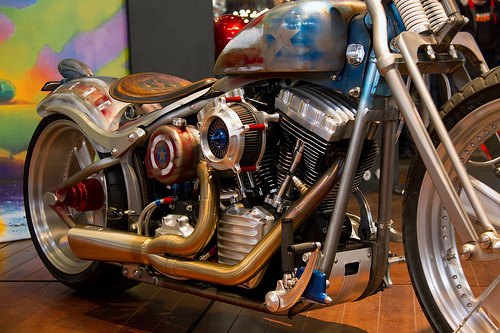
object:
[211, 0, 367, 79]
gas tank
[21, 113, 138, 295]
wheel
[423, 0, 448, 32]
spring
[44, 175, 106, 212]
joint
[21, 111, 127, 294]
tire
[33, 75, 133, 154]
wheel cover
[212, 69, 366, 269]
chopper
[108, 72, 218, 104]
seat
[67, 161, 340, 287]
tubing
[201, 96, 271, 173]
air filter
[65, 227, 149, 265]
pipe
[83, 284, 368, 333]
shadow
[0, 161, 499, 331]
ground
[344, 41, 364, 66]
bolt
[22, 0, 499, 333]
bike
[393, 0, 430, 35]
spring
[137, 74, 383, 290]
engine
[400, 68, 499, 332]
tire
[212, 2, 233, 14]
shelf